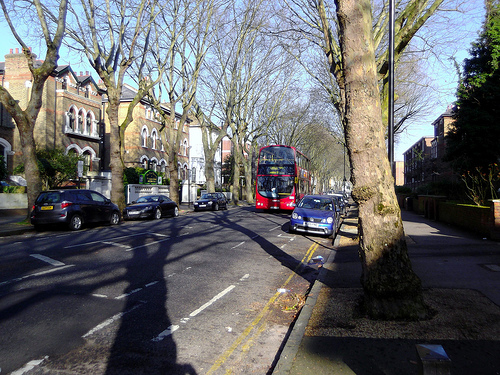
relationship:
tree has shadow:
[322, 3, 420, 316] [183, 204, 360, 296]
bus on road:
[253, 148, 322, 213] [4, 197, 340, 374]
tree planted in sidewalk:
[322, 3, 420, 316] [276, 187, 499, 374]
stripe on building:
[54, 89, 101, 108] [4, 50, 190, 207]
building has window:
[4, 50, 190, 207] [63, 105, 78, 133]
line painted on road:
[147, 272, 250, 349] [4, 197, 340, 374]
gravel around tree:
[300, 286, 499, 341] [322, 3, 420, 316]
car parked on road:
[285, 188, 344, 238] [4, 197, 340, 374]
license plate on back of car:
[40, 203, 57, 211] [26, 187, 125, 228]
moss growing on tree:
[354, 178, 380, 204] [322, 3, 420, 316]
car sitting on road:
[285, 188, 344, 238] [4, 197, 340, 374]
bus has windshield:
[253, 148, 322, 213] [256, 173, 295, 193]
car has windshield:
[285, 188, 344, 238] [299, 195, 344, 213]